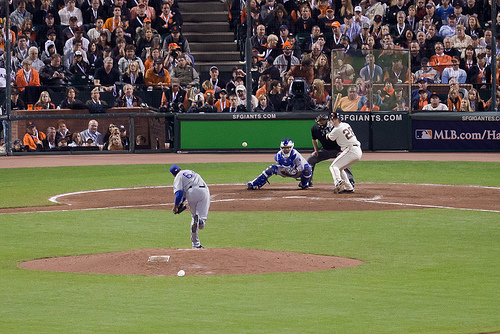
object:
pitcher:
[170, 164, 211, 249]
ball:
[240, 141, 248, 148]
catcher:
[245, 137, 314, 194]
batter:
[325, 110, 365, 194]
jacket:
[15, 67, 43, 87]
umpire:
[307, 113, 356, 193]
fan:
[40, 39, 60, 65]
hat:
[43, 39, 58, 55]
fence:
[329, 47, 413, 113]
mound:
[17, 244, 366, 278]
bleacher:
[0, 2, 499, 153]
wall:
[9, 109, 500, 151]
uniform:
[170, 169, 211, 244]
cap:
[167, 163, 182, 175]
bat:
[329, 91, 343, 110]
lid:
[330, 111, 340, 119]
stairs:
[176, 0, 247, 77]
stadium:
[1, 1, 499, 112]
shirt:
[311, 125, 342, 150]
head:
[168, 165, 183, 176]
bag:
[175, 269, 190, 278]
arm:
[173, 177, 185, 208]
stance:
[329, 148, 364, 193]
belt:
[341, 143, 363, 150]